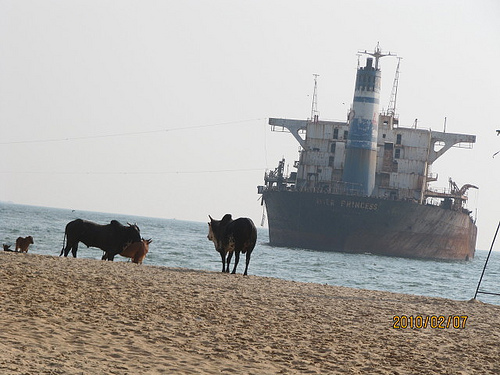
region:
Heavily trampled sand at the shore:
[24, 250, 218, 354]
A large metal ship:
[265, 45, 483, 268]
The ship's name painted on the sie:
[306, 183, 395, 218]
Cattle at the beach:
[52, 216, 265, 282]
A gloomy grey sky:
[44, 29, 197, 137]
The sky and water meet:
[29, 165, 194, 227]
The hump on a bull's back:
[104, 217, 125, 231]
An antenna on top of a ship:
[368, 55, 404, 139]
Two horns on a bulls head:
[127, 217, 147, 238]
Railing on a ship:
[327, 177, 377, 200]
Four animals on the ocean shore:
[0, 212, 258, 277]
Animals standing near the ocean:
[0, 210, 498, 371]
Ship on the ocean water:
[255, 40, 475, 265]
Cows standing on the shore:
[55, 206, 292, 363]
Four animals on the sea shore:
[2, 210, 259, 292]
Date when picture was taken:
[386, 310, 466, 335]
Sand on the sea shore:
[0, 267, 491, 368]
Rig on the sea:
[255, 40, 477, 265]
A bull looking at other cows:
[205, 210, 257, 275]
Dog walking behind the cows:
[11, 231, 34, 257]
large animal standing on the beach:
[185, 206, 277, 279]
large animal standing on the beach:
[10, 224, 40, 252]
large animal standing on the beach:
[45, 214, 147, 269]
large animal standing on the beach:
[104, 228, 159, 273]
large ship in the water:
[245, 37, 494, 275]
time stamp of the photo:
[375, 298, 485, 353]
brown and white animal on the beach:
[195, 201, 272, 284]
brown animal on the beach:
[109, 231, 163, 271]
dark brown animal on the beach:
[47, 216, 144, 266]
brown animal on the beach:
[0, 226, 46, 258]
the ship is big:
[233, 26, 496, 291]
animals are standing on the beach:
[9, 202, 277, 307]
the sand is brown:
[4, 243, 490, 359]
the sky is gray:
[3, 1, 487, 223]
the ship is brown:
[243, 49, 483, 283]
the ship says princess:
[288, 182, 405, 229]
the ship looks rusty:
[260, 43, 490, 281]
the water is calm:
[4, 198, 495, 310]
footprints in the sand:
[13, 250, 480, 374]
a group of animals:
[4, 195, 281, 290]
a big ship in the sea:
[271, 34, 481, 272]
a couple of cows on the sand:
[40, 194, 263, 281]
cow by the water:
[16, 231, 45, 261]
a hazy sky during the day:
[39, 61, 253, 170]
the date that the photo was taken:
[379, 298, 481, 339]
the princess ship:
[306, 191, 406, 218]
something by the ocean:
[51, 171, 76, 216]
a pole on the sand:
[472, 121, 497, 303]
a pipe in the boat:
[334, 57, 394, 203]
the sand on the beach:
[19, 251, 151, 373]